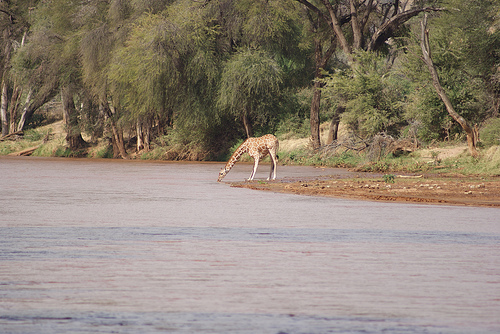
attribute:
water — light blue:
[269, 207, 364, 285]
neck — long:
[223, 144, 249, 171]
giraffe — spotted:
[215, 133, 281, 185]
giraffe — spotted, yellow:
[211, 139, 287, 189]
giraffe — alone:
[218, 132, 282, 179]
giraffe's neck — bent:
[222, 141, 250, 173]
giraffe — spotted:
[217, 131, 287, 189]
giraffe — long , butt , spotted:
[216, 132, 278, 183]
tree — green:
[224, 56, 279, 130]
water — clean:
[120, 255, 428, 298]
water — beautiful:
[138, 230, 450, 300]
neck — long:
[220, 143, 242, 173]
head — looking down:
[215, 168, 226, 185]